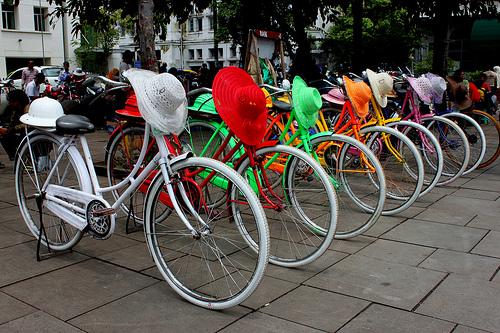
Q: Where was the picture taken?
A: It was taken at the sidewalk.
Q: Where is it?
A: This is at the sidewalk.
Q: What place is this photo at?
A: It is at the sidewalk.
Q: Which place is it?
A: It is a sidewalk.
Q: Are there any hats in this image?
A: Yes, there is a hat.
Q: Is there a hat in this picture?
A: Yes, there is a hat.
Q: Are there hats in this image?
A: Yes, there is a hat.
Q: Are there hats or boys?
A: Yes, there is a hat.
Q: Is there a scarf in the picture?
A: No, there are no scarves.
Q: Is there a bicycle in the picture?
A: Yes, there is a bicycle.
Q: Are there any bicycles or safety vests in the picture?
A: Yes, there is a bicycle.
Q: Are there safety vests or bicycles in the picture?
A: Yes, there is a bicycle.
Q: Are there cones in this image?
A: No, there are no cones.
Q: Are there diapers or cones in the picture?
A: No, there are no cones or diapers.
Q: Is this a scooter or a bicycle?
A: This is a bicycle.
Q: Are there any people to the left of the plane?
A: Yes, there are people to the left of the plane.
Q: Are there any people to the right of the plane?
A: No, the people are to the left of the plane.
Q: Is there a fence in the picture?
A: No, there are no fences.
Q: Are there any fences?
A: No, there are no fences.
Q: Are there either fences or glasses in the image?
A: No, there are no fences or glasses.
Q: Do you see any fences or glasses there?
A: No, there are no fences or glasses.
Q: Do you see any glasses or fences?
A: No, there are no fences or glasses.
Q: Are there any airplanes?
A: Yes, there is an airplane.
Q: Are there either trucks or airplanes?
A: Yes, there is an airplane.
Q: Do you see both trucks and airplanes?
A: No, there is an airplane but no trucks.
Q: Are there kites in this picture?
A: No, there are no kites.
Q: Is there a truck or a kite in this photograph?
A: No, there are no kites or trucks.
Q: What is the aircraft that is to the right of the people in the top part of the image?
A: The aircraft is an airplane.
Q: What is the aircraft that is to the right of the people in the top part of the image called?
A: The aircraft is an airplane.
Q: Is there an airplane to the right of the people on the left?
A: Yes, there is an airplane to the right of the people.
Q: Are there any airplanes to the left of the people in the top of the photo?
A: No, the airplane is to the right of the people.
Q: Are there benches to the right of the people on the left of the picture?
A: No, there is an airplane to the right of the people.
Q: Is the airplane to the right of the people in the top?
A: Yes, the airplane is to the right of the people.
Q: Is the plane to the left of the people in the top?
A: No, the plane is to the right of the people.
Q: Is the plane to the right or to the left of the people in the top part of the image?
A: The plane is to the right of the people.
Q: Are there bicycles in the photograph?
A: Yes, there is a bicycle.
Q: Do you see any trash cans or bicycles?
A: Yes, there is a bicycle.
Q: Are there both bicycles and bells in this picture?
A: No, there is a bicycle but no bells.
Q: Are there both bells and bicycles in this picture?
A: No, there is a bicycle but no bells.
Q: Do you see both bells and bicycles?
A: No, there is a bicycle but no bells.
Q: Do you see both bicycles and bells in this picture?
A: No, there is a bicycle but no bells.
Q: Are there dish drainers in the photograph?
A: No, there are no dish drainers.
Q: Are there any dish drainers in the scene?
A: No, there are no dish drainers.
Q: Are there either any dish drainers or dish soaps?
A: No, there are no dish drainers or dish soaps.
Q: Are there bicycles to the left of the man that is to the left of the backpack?
A: Yes, there is a bicycle to the left of the man.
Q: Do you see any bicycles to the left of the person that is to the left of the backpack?
A: Yes, there is a bicycle to the left of the man.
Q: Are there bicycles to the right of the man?
A: No, the bicycle is to the left of the man.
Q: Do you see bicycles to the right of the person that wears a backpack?
A: No, the bicycle is to the left of the man.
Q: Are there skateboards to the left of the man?
A: No, there is a bicycle to the left of the man.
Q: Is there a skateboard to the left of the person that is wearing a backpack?
A: No, there is a bicycle to the left of the man.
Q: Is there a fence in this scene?
A: No, there are no fences.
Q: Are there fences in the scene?
A: No, there are no fences.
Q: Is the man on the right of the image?
A: Yes, the man is on the right of the image.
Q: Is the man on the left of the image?
A: No, the man is on the right of the image.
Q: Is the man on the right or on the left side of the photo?
A: The man is on the right of the image.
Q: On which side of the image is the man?
A: The man is on the right of the image.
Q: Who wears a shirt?
A: The man wears a shirt.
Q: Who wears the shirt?
A: The man wears a shirt.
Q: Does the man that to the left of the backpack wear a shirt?
A: Yes, the man wears a shirt.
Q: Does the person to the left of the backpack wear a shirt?
A: Yes, the man wears a shirt.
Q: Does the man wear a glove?
A: No, the man wears a shirt.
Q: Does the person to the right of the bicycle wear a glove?
A: No, the man wears a shirt.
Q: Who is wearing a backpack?
A: The man is wearing a backpack.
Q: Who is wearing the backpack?
A: The man is wearing a backpack.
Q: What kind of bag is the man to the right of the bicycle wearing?
A: The man is wearing a backpack.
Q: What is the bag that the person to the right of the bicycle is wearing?
A: The bag is a backpack.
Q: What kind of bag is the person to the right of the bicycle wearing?
A: The man is wearing a backpack.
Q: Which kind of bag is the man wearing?
A: The man is wearing a backpack.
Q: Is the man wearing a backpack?
A: Yes, the man is wearing a backpack.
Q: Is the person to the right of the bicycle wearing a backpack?
A: Yes, the man is wearing a backpack.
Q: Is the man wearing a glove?
A: No, the man is wearing a backpack.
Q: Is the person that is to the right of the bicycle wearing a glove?
A: No, the man is wearing a backpack.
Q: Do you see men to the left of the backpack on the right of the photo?
A: Yes, there is a man to the left of the backpack.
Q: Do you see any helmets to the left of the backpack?
A: No, there is a man to the left of the backpack.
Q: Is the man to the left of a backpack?
A: Yes, the man is to the left of a backpack.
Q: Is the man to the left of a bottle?
A: No, the man is to the left of a backpack.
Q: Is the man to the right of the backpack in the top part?
A: No, the man is to the left of the backpack.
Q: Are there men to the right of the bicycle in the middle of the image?
A: Yes, there is a man to the right of the bicycle.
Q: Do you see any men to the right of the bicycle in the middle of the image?
A: Yes, there is a man to the right of the bicycle.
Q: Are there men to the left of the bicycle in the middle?
A: No, the man is to the right of the bicycle.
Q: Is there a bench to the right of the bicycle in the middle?
A: No, there is a man to the right of the bicycle.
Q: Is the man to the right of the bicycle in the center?
A: Yes, the man is to the right of the bicycle.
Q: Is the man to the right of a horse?
A: No, the man is to the right of the bicycle.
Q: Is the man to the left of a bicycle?
A: No, the man is to the right of a bicycle.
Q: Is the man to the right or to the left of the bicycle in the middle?
A: The man is to the right of the bicycle.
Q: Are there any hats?
A: Yes, there is a hat.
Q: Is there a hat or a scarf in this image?
A: Yes, there is a hat.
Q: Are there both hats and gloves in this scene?
A: No, there is a hat but no gloves.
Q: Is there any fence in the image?
A: No, there are no fences.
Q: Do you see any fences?
A: No, there are no fences.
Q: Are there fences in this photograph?
A: No, there are no fences.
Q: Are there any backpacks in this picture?
A: Yes, there is a backpack.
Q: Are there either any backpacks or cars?
A: Yes, there is a backpack.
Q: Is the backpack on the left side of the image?
A: No, the backpack is on the right of the image.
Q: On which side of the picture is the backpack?
A: The backpack is on the right of the image.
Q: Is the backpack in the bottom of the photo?
A: No, the backpack is in the top of the image.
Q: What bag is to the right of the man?
A: The bag is a backpack.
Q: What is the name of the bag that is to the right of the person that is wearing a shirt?
A: The bag is a backpack.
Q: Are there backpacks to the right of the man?
A: Yes, there is a backpack to the right of the man.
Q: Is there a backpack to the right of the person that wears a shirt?
A: Yes, there is a backpack to the right of the man.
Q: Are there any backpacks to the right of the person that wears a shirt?
A: Yes, there is a backpack to the right of the man.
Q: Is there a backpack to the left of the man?
A: No, the backpack is to the right of the man.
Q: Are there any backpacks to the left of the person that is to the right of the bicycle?
A: No, the backpack is to the right of the man.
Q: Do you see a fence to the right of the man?
A: No, there is a backpack to the right of the man.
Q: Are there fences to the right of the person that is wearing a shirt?
A: No, there is a backpack to the right of the man.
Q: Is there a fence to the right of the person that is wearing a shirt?
A: No, there is a backpack to the right of the man.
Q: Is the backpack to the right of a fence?
A: No, the backpack is to the right of a man.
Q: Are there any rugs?
A: No, there are no rugs.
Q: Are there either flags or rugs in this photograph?
A: No, there are no rugs or flags.